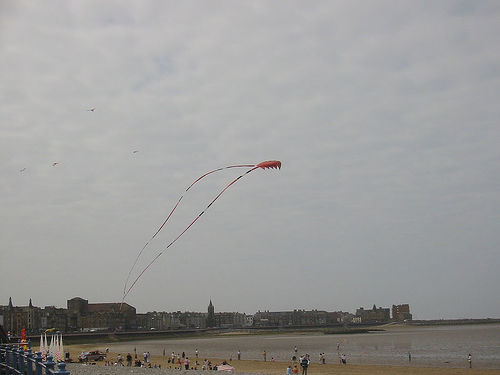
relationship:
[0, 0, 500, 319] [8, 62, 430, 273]
clouds in sky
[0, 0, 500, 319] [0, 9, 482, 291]
clouds in sky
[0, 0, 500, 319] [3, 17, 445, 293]
clouds in sky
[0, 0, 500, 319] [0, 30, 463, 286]
clouds in sky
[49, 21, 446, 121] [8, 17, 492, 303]
clouds in sky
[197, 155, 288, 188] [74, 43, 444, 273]
kite in sky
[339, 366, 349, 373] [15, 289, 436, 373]
sand on coast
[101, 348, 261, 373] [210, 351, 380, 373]
tourists on beach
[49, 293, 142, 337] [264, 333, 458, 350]
building on water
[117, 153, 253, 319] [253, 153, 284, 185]
tail hanging from kite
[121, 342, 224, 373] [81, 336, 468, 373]
crowd on beach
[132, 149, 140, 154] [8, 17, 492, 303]
bird flying in sky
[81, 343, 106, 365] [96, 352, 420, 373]
automobile on sand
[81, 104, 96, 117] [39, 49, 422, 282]
bird flying in sky